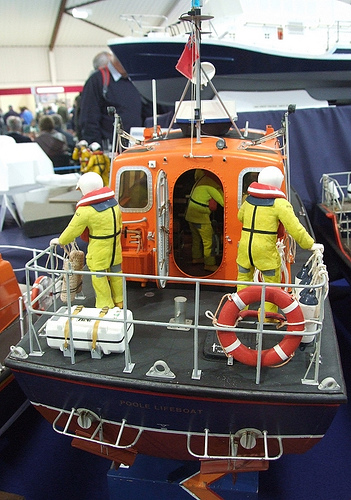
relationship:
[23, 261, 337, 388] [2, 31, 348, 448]
guardrail over boat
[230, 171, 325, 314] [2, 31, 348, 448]
worker on boat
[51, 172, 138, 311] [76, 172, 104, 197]
man wearing a helmet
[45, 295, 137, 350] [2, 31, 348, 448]
white case on boat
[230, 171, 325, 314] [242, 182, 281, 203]
worker wearing a life vest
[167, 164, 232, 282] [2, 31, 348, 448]
door into boat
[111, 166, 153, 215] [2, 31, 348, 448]
window on boat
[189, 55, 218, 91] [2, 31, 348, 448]
speaker on a boat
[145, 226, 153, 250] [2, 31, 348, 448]
handles on boat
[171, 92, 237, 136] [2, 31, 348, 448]
blue box on boat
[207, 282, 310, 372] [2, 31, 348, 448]
lifesaver on boat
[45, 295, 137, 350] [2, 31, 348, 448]
first aid kit on boat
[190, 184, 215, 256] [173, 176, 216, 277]
man in galley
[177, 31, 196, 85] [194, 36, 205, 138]
flag on pole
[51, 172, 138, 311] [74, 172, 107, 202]
person wearing a helmet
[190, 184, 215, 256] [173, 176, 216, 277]
person in boat cabin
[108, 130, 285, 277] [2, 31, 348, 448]
cabin on a boat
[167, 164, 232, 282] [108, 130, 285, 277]
door to cabin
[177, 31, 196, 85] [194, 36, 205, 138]
flag on a pole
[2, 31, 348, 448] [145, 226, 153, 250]
boat has handles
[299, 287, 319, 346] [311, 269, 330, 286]
bag underneath handle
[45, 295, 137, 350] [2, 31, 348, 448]
white box on boat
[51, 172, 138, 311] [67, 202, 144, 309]
man in a yellow suit